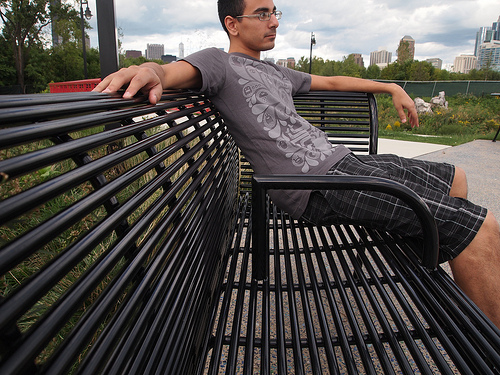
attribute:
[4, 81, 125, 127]
pipe — surface 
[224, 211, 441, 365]
bottom — wire 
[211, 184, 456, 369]
bottom — wire 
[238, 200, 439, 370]
bottom — wire 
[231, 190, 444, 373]
bottom — wire 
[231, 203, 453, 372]
bottom — wire 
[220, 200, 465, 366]
bottom — wire 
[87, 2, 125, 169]
pole — metal 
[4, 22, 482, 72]
horizon — city skyline  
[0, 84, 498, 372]
bench — metal pipes, black, wire bottom, curved pole 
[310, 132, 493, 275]
shorts — plaid, black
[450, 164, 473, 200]
knee — bent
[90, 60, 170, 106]
hand — fingers , pointing down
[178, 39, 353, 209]
shirt — grey, white, short sleeved tee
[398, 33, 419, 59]
building — City , background.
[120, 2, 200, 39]
sky — cloudy, blue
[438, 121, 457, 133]
grass — green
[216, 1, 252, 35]
hair — black